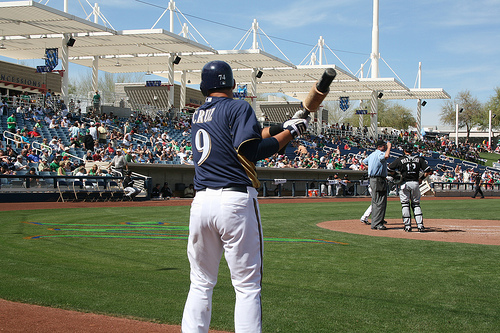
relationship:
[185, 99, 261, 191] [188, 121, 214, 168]
shirt has number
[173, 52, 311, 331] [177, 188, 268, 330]
player wearing pants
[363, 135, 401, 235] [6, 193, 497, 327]
man talking on field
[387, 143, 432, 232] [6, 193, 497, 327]
catcher talking on field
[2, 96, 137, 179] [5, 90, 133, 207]
people in their seats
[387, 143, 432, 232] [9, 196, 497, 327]
catcher standing in dirt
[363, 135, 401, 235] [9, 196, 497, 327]
man standing in dirt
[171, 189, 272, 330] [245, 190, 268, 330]
pants has line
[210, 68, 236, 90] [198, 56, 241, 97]
number on helmet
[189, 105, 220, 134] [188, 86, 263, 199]
lettering on shirt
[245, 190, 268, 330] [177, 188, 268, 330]
line on pants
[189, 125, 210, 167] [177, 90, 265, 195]
number on shirt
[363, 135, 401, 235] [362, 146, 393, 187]
man wearing shirt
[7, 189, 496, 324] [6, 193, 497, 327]
grass in field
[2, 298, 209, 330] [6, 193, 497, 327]
dirt on field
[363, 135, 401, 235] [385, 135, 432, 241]
man talking to catcher